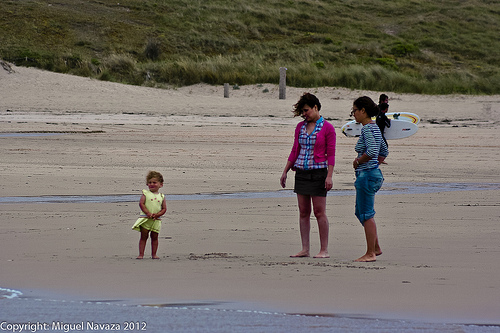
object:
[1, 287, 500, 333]
ocean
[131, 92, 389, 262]
group beach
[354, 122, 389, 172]
shirt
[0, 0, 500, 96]
field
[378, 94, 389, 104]
surfer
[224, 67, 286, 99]
poles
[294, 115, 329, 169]
shirt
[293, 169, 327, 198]
skirt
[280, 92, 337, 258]
lady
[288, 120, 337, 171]
pink sweater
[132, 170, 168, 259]
child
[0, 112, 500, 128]
dirt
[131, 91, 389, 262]
everyone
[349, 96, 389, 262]
girl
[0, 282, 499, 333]
shore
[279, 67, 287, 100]
pillar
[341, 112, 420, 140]
surfboards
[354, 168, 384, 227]
capris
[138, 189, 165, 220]
shirt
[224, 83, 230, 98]
pillar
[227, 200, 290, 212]
wet sand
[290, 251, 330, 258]
feet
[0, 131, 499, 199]
sand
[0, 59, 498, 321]
beach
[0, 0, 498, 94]
green meadow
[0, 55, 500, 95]
distance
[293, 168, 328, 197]
shorts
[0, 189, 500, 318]
sand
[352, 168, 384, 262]
leg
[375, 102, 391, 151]
people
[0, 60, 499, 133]
sand